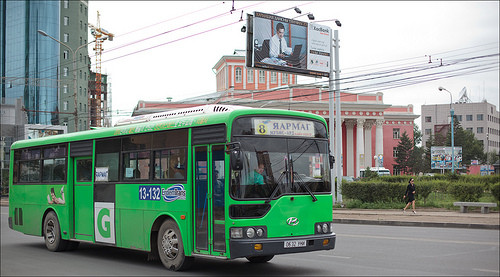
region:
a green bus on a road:
[9, 100, 356, 260]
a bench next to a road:
[449, 194, 498, 221]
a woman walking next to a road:
[389, 164, 426, 217]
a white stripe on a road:
[312, 246, 354, 264]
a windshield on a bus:
[225, 126, 343, 208]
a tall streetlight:
[434, 82, 465, 174]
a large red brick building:
[143, 43, 429, 190]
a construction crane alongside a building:
[88, 10, 122, 125]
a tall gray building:
[58, 2, 95, 132]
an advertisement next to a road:
[244, 7, 339, 78]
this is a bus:
[3, 116, 329, 257]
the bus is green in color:
[11, 108, 333, 265]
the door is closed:
[193, 144, 228, 251]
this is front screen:
[242, 137, 328, 190]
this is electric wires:
[151, 5, 203, 52]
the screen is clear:
[241, 140, 326, 190]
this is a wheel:
[155, 225, 175, 255]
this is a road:
[391, 235, 464, 266]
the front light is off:
[230, 222, 265, 237]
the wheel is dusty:
[156, 227, 176, 261]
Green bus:
[8, 102, 337, 272]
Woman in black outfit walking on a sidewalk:
[401, 175, 418, 213]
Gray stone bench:
[453, 199, 496, 216]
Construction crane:
[86, 10, 115, 126]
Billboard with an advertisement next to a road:
[243, 10, 333, 80]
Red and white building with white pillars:
[130, 51, 415, 178]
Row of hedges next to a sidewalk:
[340, 180, 495, 210]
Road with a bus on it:
[0, 200, 496, 270]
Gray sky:
[86, 0, 496, 146]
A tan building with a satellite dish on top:
[421, 85, 498, 160]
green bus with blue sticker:
[6, 105, 336, 257]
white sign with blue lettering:
[249, 110, 320, 149]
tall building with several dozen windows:
[3, 0, 99, 120]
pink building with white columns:
[133, 45, 423, 190]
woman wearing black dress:
[402, 177, 420, 207]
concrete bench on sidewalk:
[448, 200, 498, 220]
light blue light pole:
[438, 86, 460, 178]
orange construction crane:
[88, 12, 114, 125]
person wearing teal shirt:
[241, 160, 268, 185]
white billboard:
[246, 8, 343, 85]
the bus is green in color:
[111, 205, 151, 242]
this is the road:
[358, 232, 426, 267]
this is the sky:
[358, 10, 455, 45]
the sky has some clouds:
[359, 12, 431, 45]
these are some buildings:
[347, 91, 497, 161]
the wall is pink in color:
[383, 144, 390, 156]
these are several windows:
[61, 5, 91, 104]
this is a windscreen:
[246, 136, 318, 193]